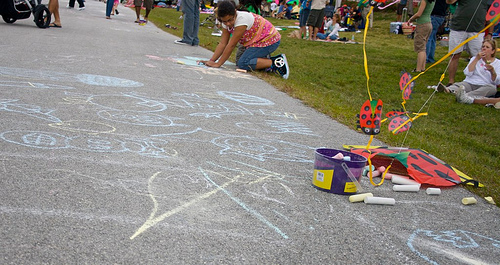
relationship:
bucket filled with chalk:
[313, 147, 364, 193] [325, 151, 355, 167]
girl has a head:
[204, 1, 294, 81] [212, 2, 246, 31]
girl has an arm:
[204, 1, 294, 81] [220, 29, 248, 70]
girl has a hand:
[204, 1, 294, 81] [204, 59, 221, 70]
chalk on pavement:
[325, 151, 355, 167] [1, 0, 497, 265]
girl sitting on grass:
[204, 1, 294, 81] [141, 2, 499, 206]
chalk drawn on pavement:
[325, 151, 355, 167] [1, 0, 497, 265]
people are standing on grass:
[134, 2, 498, 107] [141, 2, 499, 206]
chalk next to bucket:
[325, 151, 355, 167] [313, 147, 364, 193]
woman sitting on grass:
[437, 37, 497, 103] [141, 2, 499, 206]